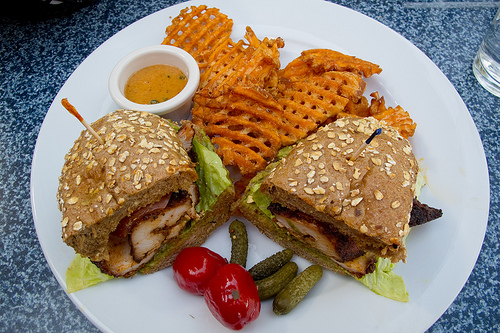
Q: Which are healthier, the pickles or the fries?
A: The pickles are healthier than the fries.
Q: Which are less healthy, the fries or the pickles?
A: The fries are less healthy than the pickles.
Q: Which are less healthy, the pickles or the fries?
A: The fries are less healthy than the pickles.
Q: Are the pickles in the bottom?
A: Yes, the pickles are in the bottom of the image.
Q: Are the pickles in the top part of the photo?
A: No, the pickles are in the bottom of the image.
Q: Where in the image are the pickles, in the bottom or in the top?
A: The pickles are in the bottom of the image.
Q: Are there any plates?
A: Yes, there is a plate.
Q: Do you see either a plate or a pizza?
A: Yes, there is a plate.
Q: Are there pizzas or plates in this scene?
A: Yes, there is a plate.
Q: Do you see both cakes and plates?
A: No, there is a plate but no cakes.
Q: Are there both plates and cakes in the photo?
A: No, there is a plate but no cakes.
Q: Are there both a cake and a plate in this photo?
A: No, there is a plate but no cakes.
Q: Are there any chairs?
A: No, there are no chairs.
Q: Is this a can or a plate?
A: This is a plate.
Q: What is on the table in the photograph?
A: The plate is on the table.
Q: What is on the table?
A: The plate is on the table.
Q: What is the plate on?
A: The plate is on the table.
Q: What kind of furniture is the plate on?
A: The plate is on the table.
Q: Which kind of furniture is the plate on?
A: The plate is on the table.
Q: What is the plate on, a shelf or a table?
A: The plate is on a table.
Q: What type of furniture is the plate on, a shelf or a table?
A: The plate is on a table.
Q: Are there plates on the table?
A: Yes, there is a plate on the table.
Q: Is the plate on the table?
A: Yes, the plate is on the table.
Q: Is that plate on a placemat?
A: No, the plate is on the table.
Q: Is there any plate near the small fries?
A: Yes, there is a plate near the French fries.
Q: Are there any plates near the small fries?
A: Yes, there is a plate near the French fries.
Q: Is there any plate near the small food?
A: Yes, there is a plate near the French fries.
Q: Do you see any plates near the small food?
A: Yes, there is a plate near the French fries.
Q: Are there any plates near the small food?
A: Yes, there is a plate near the French fries.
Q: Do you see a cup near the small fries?
A: No, there is a plate near the fries.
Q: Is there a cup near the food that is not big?
A: No, there is a plate near the fries.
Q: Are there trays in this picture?
A: No, there are no trays.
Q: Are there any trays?
A: No, there are no trays.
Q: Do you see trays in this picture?
A: No, there are no trays.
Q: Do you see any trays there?
A: No, there are no trays.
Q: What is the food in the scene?
A: The food is fries.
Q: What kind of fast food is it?
A: The food is fries.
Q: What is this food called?
A: These are fries.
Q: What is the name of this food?
A: These are fries.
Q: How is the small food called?
A: The food is fries.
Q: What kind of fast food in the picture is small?
A: The fast food is fries.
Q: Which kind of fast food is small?
A: The fast food is fries.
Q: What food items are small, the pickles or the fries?
A: The fries are small.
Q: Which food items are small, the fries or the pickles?
A: The fries are small.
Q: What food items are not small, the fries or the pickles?
A: The pickles are not small.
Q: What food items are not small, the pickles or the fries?
A: The pickles are not small.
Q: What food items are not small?
A: The food items are pickles.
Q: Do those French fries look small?
A: Yes, the French fries are small.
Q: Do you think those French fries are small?
A: Yes, the French fries are small.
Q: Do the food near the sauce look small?
A: Yes, the French fries are small.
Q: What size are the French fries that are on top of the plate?
A: The French fries are small.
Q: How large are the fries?
A: The fries are small.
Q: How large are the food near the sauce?
A: The fries are small.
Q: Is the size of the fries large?
A: No, the fries are small.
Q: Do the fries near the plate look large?
A: No, the fries are small.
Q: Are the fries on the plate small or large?
A: The French fries are small.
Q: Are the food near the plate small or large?
A: The French fries are small.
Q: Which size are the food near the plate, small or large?
A: The French fries are small.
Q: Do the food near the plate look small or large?
A: The French fries are small.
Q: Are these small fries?
A: Yes, these are small fries.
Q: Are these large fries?
A: No, these are small fries.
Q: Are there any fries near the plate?
A: Yes, there are fries near the plate.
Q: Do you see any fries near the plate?
A: Yes, there are fries near the plate.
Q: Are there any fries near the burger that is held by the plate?
A: Yes, there are fries near the burger.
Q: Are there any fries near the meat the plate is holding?
A: Yes, there are fries near the burger.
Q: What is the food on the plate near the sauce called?
A: The food is fries.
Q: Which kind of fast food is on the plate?
A: The food is fries.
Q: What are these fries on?
A: The fries are on the plate.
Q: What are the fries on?
A: The fries are on the plate.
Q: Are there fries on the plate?
A: Yes, there are fries on the plate.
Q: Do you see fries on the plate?
A: Yes, there are fries on the plate.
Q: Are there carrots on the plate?
A: No, there are fries on the plate.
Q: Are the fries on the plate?
A: Yes, the fries are on the plate.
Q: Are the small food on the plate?
A: Yes, the fries are on the plate.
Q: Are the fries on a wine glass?
A: No, the fries are on the plate.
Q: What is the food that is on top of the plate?
A: The food is fries.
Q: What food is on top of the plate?
A: The food is fries.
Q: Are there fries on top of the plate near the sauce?
A: Yes, there are fries on top of the plate.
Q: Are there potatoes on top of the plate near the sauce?
A: No, there are fries on top of the plate.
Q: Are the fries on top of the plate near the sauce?
A: Yes, the fries are on top of the plate.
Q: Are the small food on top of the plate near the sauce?
A: Yes, the fries are on top of the plate.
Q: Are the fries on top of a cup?
A: No, the fries are on top of the plate.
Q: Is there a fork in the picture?
A: No, there are no forks.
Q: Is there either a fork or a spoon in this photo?
A: No, there are no forks or spoons.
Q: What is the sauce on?
A: The sauce is on the plate.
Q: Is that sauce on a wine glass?
A: No, the sauce is on the plate.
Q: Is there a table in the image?
A: Yes, there is a table.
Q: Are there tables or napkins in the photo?
A: Yes, there is a table.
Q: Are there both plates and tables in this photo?
A: Yes, there are both a table and a plate.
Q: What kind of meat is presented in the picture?
A: The meat is a burger.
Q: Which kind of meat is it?
A: The meat is a burger.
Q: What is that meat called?
A: This is a burger.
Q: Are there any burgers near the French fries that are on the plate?
A: Yes, there is a burger near the French fries.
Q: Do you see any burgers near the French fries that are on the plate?
A: Yes, there is a burger near the French fries.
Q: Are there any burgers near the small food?
A: Yes, there is a burger near the French fries.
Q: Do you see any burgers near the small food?
A: Yes, there is a burger near the French fries.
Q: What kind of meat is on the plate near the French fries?
A: The meat is a burger.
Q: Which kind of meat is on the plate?
A: The meat is a burger.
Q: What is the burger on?
A: The burger is on the plate.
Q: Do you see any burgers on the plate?
A: Yes, there is a burger on the plate.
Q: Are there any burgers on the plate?
A: Yes, there is a burger on the plate.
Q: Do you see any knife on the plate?
A: No, there is a burger on the plate.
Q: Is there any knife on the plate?
A: No, there is a burger on the plate.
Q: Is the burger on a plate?
A: Yes, the burger is on a plate.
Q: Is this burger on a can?
A: No, the burger is on a plate.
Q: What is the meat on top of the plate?
A: The meat is a burger.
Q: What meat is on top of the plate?
A: The meat is a burger.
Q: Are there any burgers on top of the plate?
A: Yes, there is a burger on top of the plate.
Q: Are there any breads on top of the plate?
A: No, there is a burger on top of the plate.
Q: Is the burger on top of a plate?
A: Yes, the burger is on top of a plate.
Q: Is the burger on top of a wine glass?
A: No, the burger is on top of a plate.